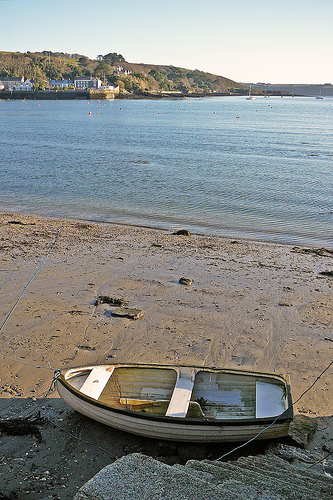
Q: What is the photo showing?
A: It is showing a shore.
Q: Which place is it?
A: It is a shore.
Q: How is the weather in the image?
A: It is clear.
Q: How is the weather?
A: It is clear.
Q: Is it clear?
A: Yes, it is clear.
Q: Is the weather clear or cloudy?
A: It is clear.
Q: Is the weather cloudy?
A: No, it is clear.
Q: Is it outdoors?
A: Yes, it is outdoors.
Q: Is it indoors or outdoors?
A: It is outdoors.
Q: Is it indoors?
A: No, it is outdoors.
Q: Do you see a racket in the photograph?
A: No, there are no rackets.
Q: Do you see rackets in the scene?
A: No, there are no rackets.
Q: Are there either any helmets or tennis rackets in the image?
A: No, there are no tennis rackets or helmets.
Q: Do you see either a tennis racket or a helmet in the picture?
A: No, there are no rackets or helmets.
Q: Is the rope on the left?
A: Yes, the rope is on the left of the image.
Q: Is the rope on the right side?
A: No, the rope is on the left of the image.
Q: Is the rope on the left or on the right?
A: The rope is on the left of the image.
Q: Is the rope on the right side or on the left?
A: The rope is on the left of the image.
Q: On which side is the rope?
A: The rope is on the left of the image.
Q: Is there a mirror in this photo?
A: No, there are no mirrors.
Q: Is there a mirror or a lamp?
A: No, there are no mirrors or lamps.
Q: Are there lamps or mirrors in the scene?
A: No, there are no mirrors or lamps.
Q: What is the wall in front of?
A: The wall is in front of the buildings.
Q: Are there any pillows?
A: No, there are no pillows.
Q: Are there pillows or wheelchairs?
A: No, there are no pillows or wheelchairs.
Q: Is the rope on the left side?
A: Yes, the rope is on the left of the image.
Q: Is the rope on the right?
A: No, the rope is on the left of the image.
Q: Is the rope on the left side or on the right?
A: The rope is on the left of the image.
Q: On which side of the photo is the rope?
A: The rope is on the left of the image.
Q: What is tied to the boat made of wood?
A: The rope is tied to the boat.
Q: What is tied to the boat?
A: The rope is tied to the boat.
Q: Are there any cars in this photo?
A: No, there are no cars.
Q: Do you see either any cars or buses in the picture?
A: No, there are no cars or buses.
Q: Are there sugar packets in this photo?
A: No, there are no sugar packets.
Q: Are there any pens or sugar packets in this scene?
A: No, there are no sugar packets or pens.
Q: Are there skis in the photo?
A: No, there are no skis.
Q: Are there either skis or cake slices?
A: No, there are no skis or cake slices.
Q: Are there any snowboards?
A: No, there are no snowboards.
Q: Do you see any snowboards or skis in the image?
A: No, there are no snowboards or skis.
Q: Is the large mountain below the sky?
A: Yes, the mountain is below the sky.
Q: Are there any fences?
A: No, there are no fences.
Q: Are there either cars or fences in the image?
A: No, there are no fences or cars.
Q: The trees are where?
A: The trees are on the mountain.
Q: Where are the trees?
A: The trees are on the mountain.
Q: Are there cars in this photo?
A: No, there are no cars.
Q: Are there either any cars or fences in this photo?
A: No, there are no cars or fences.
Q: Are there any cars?
A: No, there are no cars.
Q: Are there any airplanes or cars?
A: No, there are no cars or airplanes.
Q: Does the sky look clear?
A: Yes, the sky is clear.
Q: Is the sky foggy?
A: No, the sky is clear.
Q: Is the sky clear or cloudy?
A: The sky is clear.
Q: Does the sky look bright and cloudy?
A: No, the sky is bright but clear.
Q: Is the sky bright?
A: Yes, the sky is bright.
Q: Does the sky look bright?
A: Yes, the sky is bright.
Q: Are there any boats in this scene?
A: Yes, there is a boat.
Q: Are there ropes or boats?
A: Yes, there is a boat.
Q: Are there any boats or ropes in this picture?
A: Yes, there is a boat.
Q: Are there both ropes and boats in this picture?
A: Yes, there are both a boat and a rope.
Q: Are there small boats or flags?
A: Yes, there is a small boat.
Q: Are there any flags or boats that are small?
A: Yes, the boat is small.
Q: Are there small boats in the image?
A: Yes, there is a small boat.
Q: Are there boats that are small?
A: Yes, there is a boat that is small.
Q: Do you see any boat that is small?
A: Yes, there is a boat that is small.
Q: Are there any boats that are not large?
A: Yes, there is a small boat.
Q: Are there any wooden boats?
A: Yes, there is a wood boat.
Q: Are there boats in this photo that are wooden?
A: Yes, there is a boat that is wooden.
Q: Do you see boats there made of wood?
A: Yes, there is a boat that is made of wood.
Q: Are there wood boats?
A: Yes, there is a boat that is made of wood.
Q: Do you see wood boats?
A: Yes, there is a boat that is made of wood.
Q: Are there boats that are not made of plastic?
A: Yes, there is a boat that is made of wood.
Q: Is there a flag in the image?
A: No, there are no flags.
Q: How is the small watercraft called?
A: The watercraft is a boat.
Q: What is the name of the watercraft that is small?
A: The watercraft is a boat.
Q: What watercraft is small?
A: The watercraft is a boat.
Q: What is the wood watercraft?
A: The watercraft is a boat.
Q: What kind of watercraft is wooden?
A: The watercraft is a boat.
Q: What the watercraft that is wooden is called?
A: The watercraft is a boat.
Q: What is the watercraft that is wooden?
A: The watercraft is a boat.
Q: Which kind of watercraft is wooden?
A: The watercraft is a boat.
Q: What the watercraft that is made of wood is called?
A: The watercraft is a boat.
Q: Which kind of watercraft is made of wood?
A: The watercraft is a boat.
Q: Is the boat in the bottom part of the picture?
A: Yes, the boat is in the bottom of the image.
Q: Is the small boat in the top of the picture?
A: No, the boat is in the bottom of the image.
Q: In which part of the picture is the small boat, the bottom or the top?
A: The boat is in the bottom of the image.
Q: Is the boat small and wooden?
A: Yes, the boat is small and wooden.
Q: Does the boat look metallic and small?
A: No, the boat is small but wooden.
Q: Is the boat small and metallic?
A: No, the boat is small but wooden.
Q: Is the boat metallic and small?
A: No, the boat is small but wooden.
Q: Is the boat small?
A: Yes, the boat is small.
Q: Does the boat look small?
A: Yes, the boat is small.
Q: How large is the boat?
A: The boat is small.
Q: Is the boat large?
A: No, the boat is small.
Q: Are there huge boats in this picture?
A: No, there is a boat but it is small.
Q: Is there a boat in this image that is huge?
A: No, there is a boat but it is small.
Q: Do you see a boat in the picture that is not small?
A: No, there is a boat but it is small.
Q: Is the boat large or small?
A: The boat is small.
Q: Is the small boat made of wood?
A: Yes, the boat is made of wood.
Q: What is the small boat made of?
A: The boat is made of wood.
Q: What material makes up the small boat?
A: The boat is made of wood.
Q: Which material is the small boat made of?
A: The boat is made of wood.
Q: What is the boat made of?
A: The boat is made of wood.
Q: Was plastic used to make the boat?
A: No, the boat is made of wood.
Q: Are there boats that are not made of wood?
A: No, there is a boat but it is made of wood.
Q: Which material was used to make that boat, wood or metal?
A: The boat is made of wood.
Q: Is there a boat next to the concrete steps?
A: Yes, there is a boat next to the steps.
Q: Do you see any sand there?
A: Yes, there is sand.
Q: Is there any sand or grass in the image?
A: Yes, there is sand.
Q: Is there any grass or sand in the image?
A: Yes, there is sand.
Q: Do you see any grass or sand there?
A: Yes, there is sand.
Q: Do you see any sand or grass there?
A: Yes, there is sand.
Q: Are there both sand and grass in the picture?
A: No, there is sand but no grass.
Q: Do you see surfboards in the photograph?
A: No, there are no surfboards.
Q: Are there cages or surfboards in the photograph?
A: No, there are no surfboards or cages.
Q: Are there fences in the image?
A: No, there are no fences.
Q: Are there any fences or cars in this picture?
A: No, there are no fences or cars.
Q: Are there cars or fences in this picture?
A: No, there are no fences or cars.